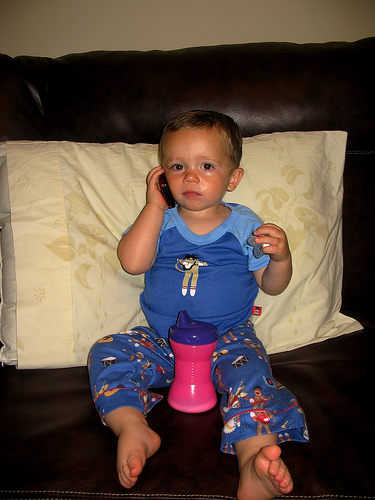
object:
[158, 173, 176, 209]
phone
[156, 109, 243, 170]
hair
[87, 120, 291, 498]
boy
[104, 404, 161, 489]
no socks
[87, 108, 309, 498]
child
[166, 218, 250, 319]
blue shirt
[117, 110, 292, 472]
boy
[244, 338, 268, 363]
picture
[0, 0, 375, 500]
picture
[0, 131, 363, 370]
pillow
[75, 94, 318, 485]
boy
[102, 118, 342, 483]
boy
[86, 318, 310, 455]
pants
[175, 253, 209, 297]
picture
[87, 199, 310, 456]
pajama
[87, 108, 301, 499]
child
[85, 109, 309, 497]
boy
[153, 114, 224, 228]
boy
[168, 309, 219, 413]
sippy cup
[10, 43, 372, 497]
bed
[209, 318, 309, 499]
legs